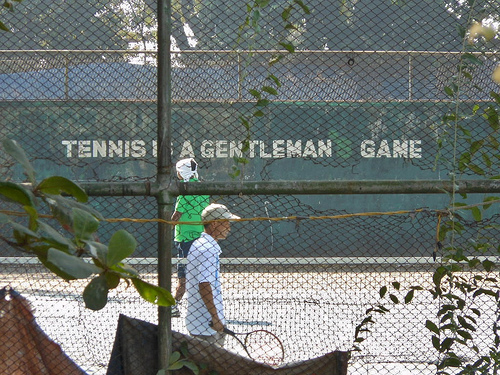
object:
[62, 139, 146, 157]
letters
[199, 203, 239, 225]
hat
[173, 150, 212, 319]
woman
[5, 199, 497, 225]
cord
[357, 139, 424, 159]
letters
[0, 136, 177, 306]
leaves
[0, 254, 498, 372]
court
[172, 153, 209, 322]
person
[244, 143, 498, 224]
hole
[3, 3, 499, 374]
fence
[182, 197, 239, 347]
man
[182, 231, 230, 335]
shirt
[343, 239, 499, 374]
branches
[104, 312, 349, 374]
tarp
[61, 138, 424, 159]
letters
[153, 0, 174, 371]
pole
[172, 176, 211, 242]
shirt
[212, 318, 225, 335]
hand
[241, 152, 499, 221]
rip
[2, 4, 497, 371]
netting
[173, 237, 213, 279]
shorts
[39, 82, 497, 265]
wall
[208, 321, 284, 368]
racket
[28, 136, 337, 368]
branches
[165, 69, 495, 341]
fence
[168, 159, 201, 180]
towel